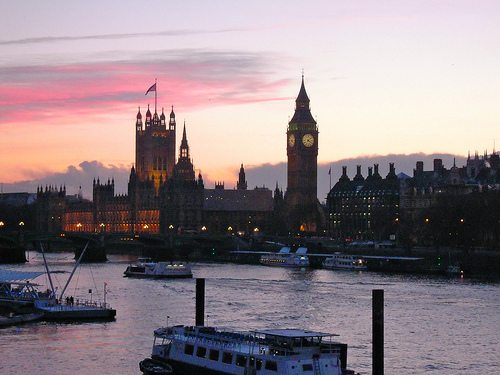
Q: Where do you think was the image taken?
A: It was taken at the town.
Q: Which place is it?
A: It is a town.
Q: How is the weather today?
A: It is clear.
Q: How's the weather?
A: It is clear.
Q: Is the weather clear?
A: Yes, it is clear.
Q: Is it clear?
A: Yes, it is clear.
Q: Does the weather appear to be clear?
A: Yes, it is clear.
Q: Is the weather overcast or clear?
A: It is clear.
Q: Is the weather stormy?
A: No, it is clear.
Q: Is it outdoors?
A: Yes, it is outdoors.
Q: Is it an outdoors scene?
A: Yes, it is outdoors.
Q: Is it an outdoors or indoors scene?
A: It is outdoors.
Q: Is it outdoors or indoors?
A: It is outdoors.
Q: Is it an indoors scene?
A: No, it is outdoors.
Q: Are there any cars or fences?
A: No, there are no cars or fences.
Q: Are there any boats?
A: Yes, there is a boat.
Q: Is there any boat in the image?
A: Yes, there is a boat.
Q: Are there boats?
A: Yes, there is a boat.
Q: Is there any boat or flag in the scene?
A: Yes, there is a boat.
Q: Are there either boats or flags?
A: Yes, there is a boat.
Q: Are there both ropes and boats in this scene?
A: No, there is a boat but no ropes.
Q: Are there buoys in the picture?
A: No, there are no buoys.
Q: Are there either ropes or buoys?
A: No, there are no buoys or ropes.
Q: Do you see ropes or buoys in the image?
A: No, there are no buoys or ropes.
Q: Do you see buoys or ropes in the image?
A: No, there are no buoys or ropes.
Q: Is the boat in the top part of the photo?
A: No, the boat is in the bottom of the image.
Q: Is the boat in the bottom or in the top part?
A: The boat is in the bottom of the image.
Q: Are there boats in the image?
A: Yes, there is a boat.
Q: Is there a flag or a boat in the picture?
A: Yes, there is a boat.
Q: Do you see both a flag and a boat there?
A: Yes, there are both a boat and a flag.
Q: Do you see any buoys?
A: No, there are no buoys.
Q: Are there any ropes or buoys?
A: No, there are no buoys or ropes.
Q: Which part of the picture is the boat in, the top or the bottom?
A: The boat is in the bottom of the image.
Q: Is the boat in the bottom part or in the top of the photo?
A: The boat is in the bottom of the image.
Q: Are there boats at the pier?
A: Yes, there is a boat at the pier.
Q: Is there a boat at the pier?
A: Yes, there is a boat at the pier.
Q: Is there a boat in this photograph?
A: Yes, there is a boat.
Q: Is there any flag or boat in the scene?
A: Yes, there is a boat.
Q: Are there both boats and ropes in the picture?
A: No, there is a boat but no ropes.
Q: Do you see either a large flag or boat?
A: Yes, there is a large boat.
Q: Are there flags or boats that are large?
A: Yes, the boat is large.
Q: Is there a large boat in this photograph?
A: Yes, there is a large boat.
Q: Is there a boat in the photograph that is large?
A: Yes, there is a boat that is large.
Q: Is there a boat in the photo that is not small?
A: Yes, there is a large boat.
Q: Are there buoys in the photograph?
A: No, there are no buoys.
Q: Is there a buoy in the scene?
A: No, there are no buoys.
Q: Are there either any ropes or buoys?
A: No, there are no buoys or ropes.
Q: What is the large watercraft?
A: The watercraft is a boat.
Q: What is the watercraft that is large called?
A: The watercraft is a boat.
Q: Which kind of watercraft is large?
A: The watercraft is a boat.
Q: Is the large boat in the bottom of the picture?
A: Yes, the boat is in the bottom of the image.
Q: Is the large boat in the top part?
A: No, the boat is in the bottom of the image.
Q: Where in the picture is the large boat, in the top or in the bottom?
A: The boat is in the bottom of the image.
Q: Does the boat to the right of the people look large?
A: Yes, the boat is large.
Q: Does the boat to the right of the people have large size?
A: Yes, the boat is large.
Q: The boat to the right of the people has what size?
A: The boat is large.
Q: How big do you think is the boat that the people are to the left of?
A: The boat is large.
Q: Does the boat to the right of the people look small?
A: No, the boat is large.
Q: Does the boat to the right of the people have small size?
A: No, the boat is large.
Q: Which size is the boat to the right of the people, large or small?
A: The boat is large.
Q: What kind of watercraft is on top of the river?
A: The watercraft is a boat.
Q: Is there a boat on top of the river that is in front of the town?
A: Yes, there is a boat on top of the river.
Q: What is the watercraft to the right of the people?
A: The watercraft is a boat.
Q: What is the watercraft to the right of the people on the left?
A: The watercraft is a boat.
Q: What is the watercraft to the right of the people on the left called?
A: The watercraft is a boat.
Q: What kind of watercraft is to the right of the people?
A: The watercraft is a boat.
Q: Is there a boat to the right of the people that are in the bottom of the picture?
A: Yes, there is a boat to the right of the people.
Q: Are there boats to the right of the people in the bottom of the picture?
A: Yes, there is a boat to the right of the people.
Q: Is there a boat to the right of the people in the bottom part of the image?
A: Yes, there is a boat to the right of the people.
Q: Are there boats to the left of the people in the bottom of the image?
A: No, the boat is to the right of the people.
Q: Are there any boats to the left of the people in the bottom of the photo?
A: No, the boat is to the right of the people.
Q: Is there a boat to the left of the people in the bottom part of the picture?
A: No, the boat is to the right of the people.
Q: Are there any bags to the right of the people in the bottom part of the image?
A: No, there is a boat to the right of the people.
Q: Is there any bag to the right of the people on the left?
A: No, there is a boat to the right of the people.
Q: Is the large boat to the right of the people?
A: Yes, the boat is to the right of the people.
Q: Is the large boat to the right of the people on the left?
A: Yes, the boat is to the right of the people.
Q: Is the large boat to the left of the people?
A: No, the boat is to the right of the people.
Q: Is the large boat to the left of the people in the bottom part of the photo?
A: No, the boat is to the right of the people.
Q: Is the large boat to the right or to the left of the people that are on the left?
A: The boat is to the right of the people.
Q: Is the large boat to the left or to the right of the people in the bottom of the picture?
A: The boat is to the right of the people.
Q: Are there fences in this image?
A: No, there are no fences.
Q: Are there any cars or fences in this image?
A: No, there are no fences or cars.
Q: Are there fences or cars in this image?
A: No, there are no fences or cars.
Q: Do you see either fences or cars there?
A: No, there are no fences or cars.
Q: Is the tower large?
A: Yes, the tower is large.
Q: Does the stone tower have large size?
A: Yes, the tower is large.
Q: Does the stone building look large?
A: Yes, the tower is large.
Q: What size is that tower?
A: The tower is large.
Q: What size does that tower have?
A: The tower has large size.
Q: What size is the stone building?
A: The tower is large.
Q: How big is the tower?
A: The tower is large.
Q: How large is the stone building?
A: The tower is large.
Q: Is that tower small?
A: No, the tower is large.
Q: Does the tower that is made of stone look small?
A: No, the tower is large.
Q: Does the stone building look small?
A: No, the tower is large.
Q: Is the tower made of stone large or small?
A: The tower is large.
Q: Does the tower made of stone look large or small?
A: The tower is large.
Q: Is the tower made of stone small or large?
A: The tower is large.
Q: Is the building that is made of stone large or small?
A: The tower is large.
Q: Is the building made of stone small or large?
A: The tower is large.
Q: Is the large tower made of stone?
A: Yes, the tower is made of stone.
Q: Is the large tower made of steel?
A: No, the tower is made of stone.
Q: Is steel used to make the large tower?
A: No, the tower is made of stone.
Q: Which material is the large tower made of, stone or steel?
A: The tower is made of stone.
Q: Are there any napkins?
A: No, there are no napkins.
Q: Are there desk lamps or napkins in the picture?
A: No, there are no napkins or desk lamps.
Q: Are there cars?
A: No, there are no cars.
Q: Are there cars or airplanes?
A: No, there are no cars or airplanes.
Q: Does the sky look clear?
A: Yes, the sky is clear.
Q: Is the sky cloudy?
A: No, the sky is clear.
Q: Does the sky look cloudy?
A: No, the sky is clear.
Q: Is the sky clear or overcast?
A: The sky is clear.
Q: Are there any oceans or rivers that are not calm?
A: No, there is a river but it is calm.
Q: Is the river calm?
A: Yes, the river is calm.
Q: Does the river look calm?
A: Yes, the river is calm.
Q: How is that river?
A: The river is calm.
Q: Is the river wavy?
A: No, the river is calm.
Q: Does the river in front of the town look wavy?
A: No, the river is calm.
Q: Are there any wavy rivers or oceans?
A: No, there is a river but it is calm.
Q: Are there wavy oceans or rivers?
A: No, there is a river but it is calm.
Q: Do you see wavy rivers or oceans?
A: No, there is a river but it is calm.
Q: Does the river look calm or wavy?
A: The river is calm.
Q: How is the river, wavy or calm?
A: The river is calm.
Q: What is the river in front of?
A: The river is in front of the town.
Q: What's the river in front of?
A: The river is in front of the town.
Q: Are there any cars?
A: No, there are no cars.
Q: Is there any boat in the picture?
A: Yes, there is a boat.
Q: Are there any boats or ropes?
A: Yes, there is a boat.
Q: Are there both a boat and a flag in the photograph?
A: Yes, there are both a boat and a flag.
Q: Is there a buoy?
A: No, there are no buoys.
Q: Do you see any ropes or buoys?
A: No, there are no buoys or ropes.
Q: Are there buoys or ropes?
A: No, there are no buoys or ropes.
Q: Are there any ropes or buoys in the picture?
A: No, there are no buoys or ropes.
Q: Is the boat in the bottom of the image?
A: Yes, the boat is in the bottom of the image.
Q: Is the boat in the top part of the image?
A: No, the boat is in the bottom of the image.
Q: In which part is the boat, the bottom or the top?
A: The boat is in the bottom of the image.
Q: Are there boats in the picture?
A: Yes, there is a boat.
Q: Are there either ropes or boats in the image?
A: Yes, there is a boat.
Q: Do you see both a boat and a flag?
A: Yes, there are both a boat and a flag.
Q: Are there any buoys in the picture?
A: No, there are no buoys.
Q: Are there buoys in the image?
A: No, there are no buoys.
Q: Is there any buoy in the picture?
A: No, there are no buoys.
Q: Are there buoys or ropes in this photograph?
A: No, there are no buoys or ropes.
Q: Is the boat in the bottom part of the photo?
A: Yes, the boat is in the bottom of the image.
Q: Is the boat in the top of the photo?
A: No, the boat is in the bottom of the image.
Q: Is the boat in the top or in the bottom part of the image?
A: The boat is in the bottom of the image.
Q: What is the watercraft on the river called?
A: The watercraft is a boat.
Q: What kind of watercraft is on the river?
A: The watercraft is a boat.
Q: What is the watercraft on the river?
A: The watercraft is a boat.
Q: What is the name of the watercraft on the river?
A: The watercraft is a boat.